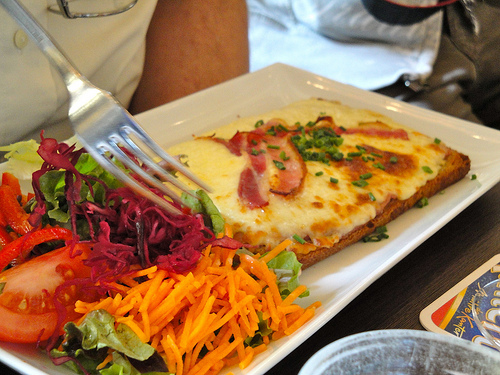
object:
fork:
[2, 1, 214, 219]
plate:
[0, 62, 500, 375]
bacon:
[194, 115, 419, 211]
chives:
[252, 112, 400, 184]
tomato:
[0, 225, 116, 349]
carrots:
[74, 223, 321, 374]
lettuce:
[0, 134, 309, 375]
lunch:
[3, 82, 476, 367]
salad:
[0, 130, 324, 375]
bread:
[150, 95, 470, 272]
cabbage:
[34, 129, 255, 374]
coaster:
[417, 254, 500, 356]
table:
[0, 83, 497, 375]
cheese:
[153, 100, 450, 253]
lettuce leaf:
[49, 310, 167, 375]